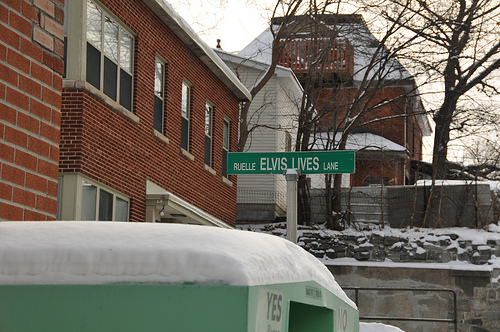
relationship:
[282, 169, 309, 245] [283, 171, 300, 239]
pole holds up sign holds green sign there is a pole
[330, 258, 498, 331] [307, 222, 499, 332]
slab is rock berm rock birm is rock slab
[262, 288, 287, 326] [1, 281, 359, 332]
letters are black letters on structure black on green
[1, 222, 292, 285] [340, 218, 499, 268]
there is snow snow on ground ground has snow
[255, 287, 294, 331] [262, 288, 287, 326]
there is a sign sign says yes yes sign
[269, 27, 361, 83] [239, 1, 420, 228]
balcony on top floor it has a balcony building has balcony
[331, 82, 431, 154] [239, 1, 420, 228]
branches have snow trees have snow snow on trees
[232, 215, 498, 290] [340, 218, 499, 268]
gray rocks have snow rocks are covered rocks are gray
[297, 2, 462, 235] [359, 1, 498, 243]
leafless trees. trees without leaves no leaves on trees.